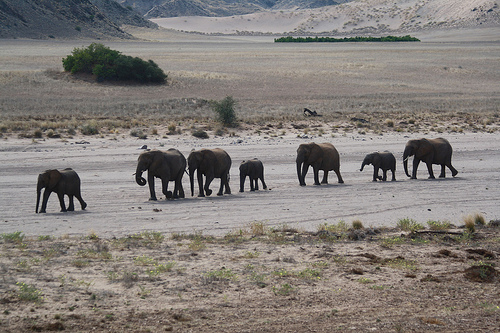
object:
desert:
[4, 20, 493, 123]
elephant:
[359, 147, 399, 182]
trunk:
[132, 170, 148, 186]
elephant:
[399, 136, 459, 178]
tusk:
[401, 150, 414, 161]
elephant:
[292, 138, 345, 188]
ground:
[211, 197, 324, 223]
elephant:
[132, 146, 187, 203]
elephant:
[188, 147, 234, 195]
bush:
[58, 38, 174, 86]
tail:
[189, 164, 196, 193]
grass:
[177, 228, 211, 252]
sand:
[163, 44, 227, 96]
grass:
[390, 216, 426, 233]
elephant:
[34, 165, 87, 214]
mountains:
[151, 0, 499, 36]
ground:
[193, 238, 337, 310]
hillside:
[0, 1, 160, 42]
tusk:
[132, 171, 140, 178]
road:
[23, 149, 229, 234]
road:
[145, 178, 429, 268]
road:
[204, 209, 417, 249]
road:
[235, 166, 363, 225]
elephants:
[133, 147, 186, 202]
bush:
[275, 33, 422, 43]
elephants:
[186, 148, 234, 197]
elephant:
[235, 157, 268, 192]